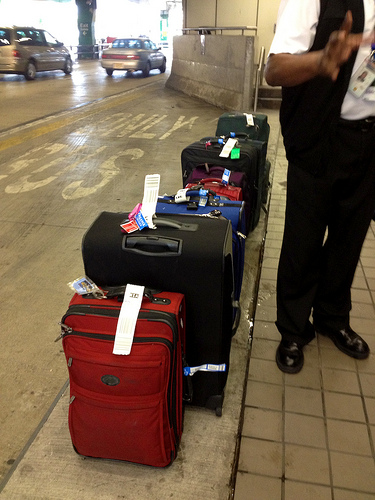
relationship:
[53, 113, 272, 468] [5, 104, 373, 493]
luggage on sidewalk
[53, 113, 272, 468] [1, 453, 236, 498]
luggage on sidewalk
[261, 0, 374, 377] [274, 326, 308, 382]
man wearing black shoe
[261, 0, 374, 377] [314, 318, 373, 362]
man wearing shoe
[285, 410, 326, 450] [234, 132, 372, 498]
square tile on floor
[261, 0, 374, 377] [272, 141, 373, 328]
man wearing pants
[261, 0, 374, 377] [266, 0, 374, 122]
man wearing shirt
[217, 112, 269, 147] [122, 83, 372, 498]
green luggage on sidewalk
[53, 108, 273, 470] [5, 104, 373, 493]
luggage on sidewalk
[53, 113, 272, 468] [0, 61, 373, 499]
luggage on sidewalk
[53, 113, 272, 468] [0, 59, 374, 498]
luggage on ground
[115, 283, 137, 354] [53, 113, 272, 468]
tag on luggage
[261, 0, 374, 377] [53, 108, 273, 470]
man standing near luggage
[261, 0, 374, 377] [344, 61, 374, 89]
man wearing badge